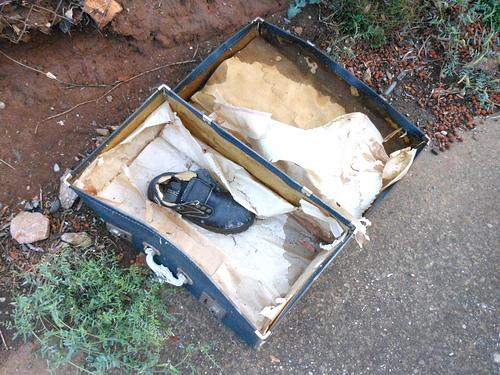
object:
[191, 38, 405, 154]
stained paper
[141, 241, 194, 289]
handle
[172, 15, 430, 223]
box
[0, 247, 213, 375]
vegetation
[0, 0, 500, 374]
ground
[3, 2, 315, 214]
sand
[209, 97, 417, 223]
paper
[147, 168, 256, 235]
shoe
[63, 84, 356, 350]
box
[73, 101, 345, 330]
paper